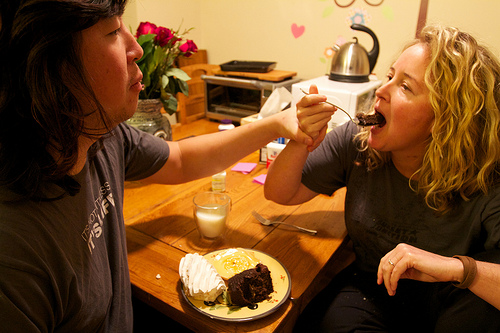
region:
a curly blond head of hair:
[428, 32, 488, 189]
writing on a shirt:
[73, 186, 113, 256]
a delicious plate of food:
[191, 247, 273, 312]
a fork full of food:
[297, 88, 389, 130]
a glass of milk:
[190, 195, 224, 239]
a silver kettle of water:
[323, 25, 380, 80]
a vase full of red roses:
[123, 24, 195, 157]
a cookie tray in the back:
[218, 57, 280, 72]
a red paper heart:
[285, 20, 309, 45]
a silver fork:
[248, 208, 328, 240]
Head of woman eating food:
[365, 21, 499, 206]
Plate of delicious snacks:
[174, 246, 294, 323]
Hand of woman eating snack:
[373, 239, 455, 297]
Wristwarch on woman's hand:
[458, 252, 474, 297]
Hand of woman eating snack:
[297, 83, 339, 144]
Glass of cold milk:
[189, 184, 229, 243]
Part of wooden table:
[148, 212, 183, 254]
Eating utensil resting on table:
[248, 206, 323, 237]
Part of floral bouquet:
[144, 20, 197, 103]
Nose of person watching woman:
[125, 25, 147, 67]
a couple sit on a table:
[11, 9, 498, 320]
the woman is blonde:
[260, 25, 499, 329]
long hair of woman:
[328, 18, 499, 255]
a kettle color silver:
[323, 19, 385, 89]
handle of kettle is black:
[345, 11, 390, 58]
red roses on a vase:
[129, 17, 202, 145]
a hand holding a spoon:
[292, 68, 387, 145]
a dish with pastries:
[168, 232, 298, 327]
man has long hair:
[5, 2, 202, 274]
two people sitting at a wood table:
[12, 9, 485, 318]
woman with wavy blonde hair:
[351, 25, 498, 196]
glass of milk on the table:
[192, 184, 246, 244]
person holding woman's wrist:
[23, 3, 485, 180]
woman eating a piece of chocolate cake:
[290, 27, 482, 149]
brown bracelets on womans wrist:
[440, 243, 480, 293]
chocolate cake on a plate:
[223, 255, 275, 320]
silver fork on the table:
[243, 205, 333, 237]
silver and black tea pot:
[317, 16, 387, 92]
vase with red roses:
[123, 13, 201, 150]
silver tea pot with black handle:
[328, 23, 380, 82]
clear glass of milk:
[191, 190, 229, 242]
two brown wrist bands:
[451, 253, 476, 290]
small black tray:
[220, 59, 275, 71]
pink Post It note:
[233, 158, 253, 174]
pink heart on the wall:
[289, 23, 304, 38]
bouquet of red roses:
[135, 21, 197, 113]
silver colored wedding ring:
[386, 260, 393, 267]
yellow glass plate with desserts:
[182, 245, 289, 316]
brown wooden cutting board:
[211, 67, 295, 82]